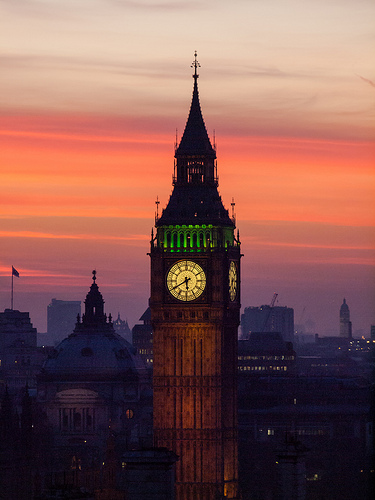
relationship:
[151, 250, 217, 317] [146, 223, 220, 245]
clock on light